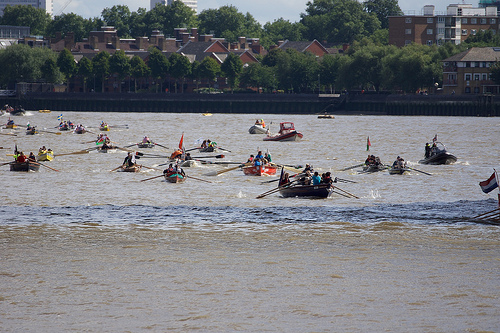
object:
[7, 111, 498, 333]
water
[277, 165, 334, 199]
boats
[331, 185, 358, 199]
paddles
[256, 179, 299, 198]
paddles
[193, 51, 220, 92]
trees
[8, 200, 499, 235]
ripples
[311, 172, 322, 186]
people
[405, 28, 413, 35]
windows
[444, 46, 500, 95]
building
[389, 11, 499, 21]
roof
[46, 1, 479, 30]
sky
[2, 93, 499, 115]
land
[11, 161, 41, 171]
boat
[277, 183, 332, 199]
boat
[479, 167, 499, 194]
flag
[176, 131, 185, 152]
flag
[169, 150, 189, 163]
boat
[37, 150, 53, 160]
boat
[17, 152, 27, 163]
person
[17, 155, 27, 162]
shirt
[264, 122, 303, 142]
boat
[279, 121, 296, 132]
cabin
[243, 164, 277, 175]
boat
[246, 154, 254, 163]
people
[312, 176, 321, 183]
shirt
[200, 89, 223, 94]
car